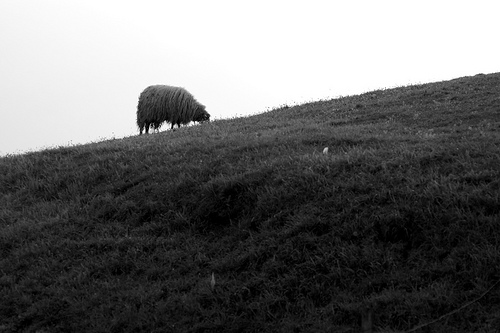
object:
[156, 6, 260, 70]
outdoors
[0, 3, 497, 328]
photo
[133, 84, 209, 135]
sheep